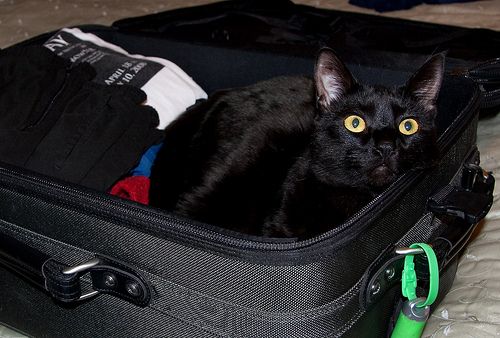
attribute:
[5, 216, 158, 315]
handle — black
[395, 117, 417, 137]
eye — orange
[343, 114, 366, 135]
eye — orange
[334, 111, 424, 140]
eyes — wide open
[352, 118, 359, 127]
black pupil — cat's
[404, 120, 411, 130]
black pupil — cat's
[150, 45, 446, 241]
cat — black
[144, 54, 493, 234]
cat — black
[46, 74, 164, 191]
clothes — blue and red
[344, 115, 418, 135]
cat eyes — yellow, cat's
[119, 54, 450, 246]
cat — black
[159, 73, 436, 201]
cat — Black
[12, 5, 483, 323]
suitcase — open, black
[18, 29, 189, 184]
clothing — folded, black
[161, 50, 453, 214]
cat — black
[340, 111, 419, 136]
eyes — open wide, cat's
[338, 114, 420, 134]
eyes — round, cat's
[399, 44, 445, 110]
ear — cat's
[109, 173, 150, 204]
clothing — red, folded 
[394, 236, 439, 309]
tag — green, luggage's